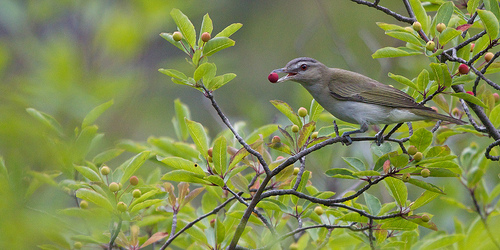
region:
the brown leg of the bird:
[340, 118, 366, 144]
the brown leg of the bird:
[373, 118, 388, 146]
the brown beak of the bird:
[269, 65, 290, 84]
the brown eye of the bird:
[301, 61, 306, 69]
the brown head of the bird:
[282, 56, 323, 84]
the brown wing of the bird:
[326, 70, 416, 107]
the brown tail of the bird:
[412, 102, 465, 126]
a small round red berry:
[268, 72, 276, 84]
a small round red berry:
[455, 62, 468, 74]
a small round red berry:
[465, 90, 475, 100]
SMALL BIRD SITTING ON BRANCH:
[266, 56, 499, 145]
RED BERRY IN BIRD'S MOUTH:
[260, 69, 281, 81]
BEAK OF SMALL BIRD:
[270, 68, 290, 80]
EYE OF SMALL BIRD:
[293, 63, 313, 73]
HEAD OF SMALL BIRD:
[266, 51, 323, 94]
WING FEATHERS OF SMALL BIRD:
[328, 78, 426, 114]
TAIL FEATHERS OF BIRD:
[417, 105, 498, 143]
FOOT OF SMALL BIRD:
[333, 120, 370, 145]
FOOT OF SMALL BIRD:
[371, 125, 405, 152]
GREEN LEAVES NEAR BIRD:
[162, 150, 219, 182]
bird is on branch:
[265, 44, 482, 169]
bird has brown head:
[287, 53, 339, 79]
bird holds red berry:
[270, 54, 284, 103]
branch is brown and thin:
[235, 119, 342, 221]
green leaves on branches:
[160, 8, 235, 114]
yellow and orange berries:
[162, 27, 221, 60]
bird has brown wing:
[352, 42, 422, 117]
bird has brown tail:
[420, 114, 465, 136]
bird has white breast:
[309, 77, 413, 128]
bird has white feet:
[321, 127, 410, 159]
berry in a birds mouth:
[264, 70, 282, 87]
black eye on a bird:
[301, 58, 311, 78]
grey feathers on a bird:
[332, 78, 359, 97]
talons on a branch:
[332, 118, 387, 150]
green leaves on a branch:
[167, 21, 229, 89]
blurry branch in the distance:
[54, 39, 111, 96]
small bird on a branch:
[261, 51, 486, 191]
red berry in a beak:
[265, 65, 285, 90]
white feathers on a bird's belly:
[343, 103, 367, 119]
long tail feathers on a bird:
[411, 108, 485, 134]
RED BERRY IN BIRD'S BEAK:
[266, 69, 279, 85]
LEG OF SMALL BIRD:
[333, 121, 370, 149]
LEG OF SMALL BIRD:
[370, 123, 408, 145]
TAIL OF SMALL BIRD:
[422, 106, 497, 142]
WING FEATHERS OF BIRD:
[329, 78, 421, 110]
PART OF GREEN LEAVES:
[159, 135, 222, 175]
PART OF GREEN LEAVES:
[74, 186, 144, 211]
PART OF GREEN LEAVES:
[390, 171, 465, 239]